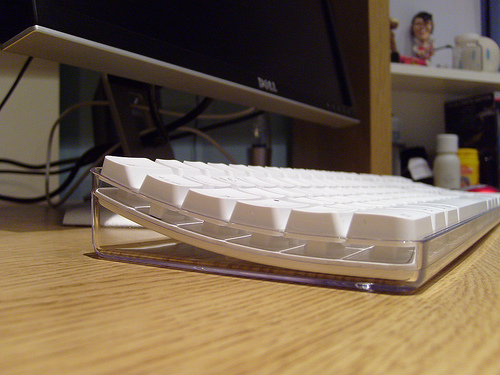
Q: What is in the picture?
A: A keyboard.